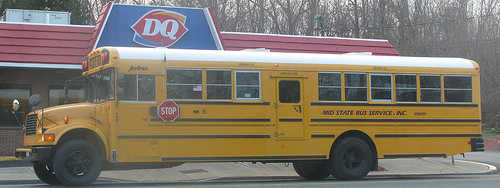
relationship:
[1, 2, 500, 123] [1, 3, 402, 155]
trees behind building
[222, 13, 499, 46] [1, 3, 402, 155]
wire behind building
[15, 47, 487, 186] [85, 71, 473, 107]
bus has windows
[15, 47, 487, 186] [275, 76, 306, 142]
bus has door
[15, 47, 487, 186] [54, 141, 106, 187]
bus has tire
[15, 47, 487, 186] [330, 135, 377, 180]
bus has tire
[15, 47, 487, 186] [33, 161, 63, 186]
bus has tire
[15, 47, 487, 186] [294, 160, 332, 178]
bus has tire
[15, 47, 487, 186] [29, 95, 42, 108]
bus has mirror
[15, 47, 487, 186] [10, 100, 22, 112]
bus has mirror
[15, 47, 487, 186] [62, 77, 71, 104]
bus has mirror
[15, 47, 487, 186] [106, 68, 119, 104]
bus has mirror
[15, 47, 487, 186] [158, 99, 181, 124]
bus h stop sign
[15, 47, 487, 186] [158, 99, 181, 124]
bus has stop sign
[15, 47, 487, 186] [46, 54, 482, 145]
bus has lights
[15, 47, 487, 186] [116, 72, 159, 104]
bus has driver's window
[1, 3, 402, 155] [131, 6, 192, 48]
building has dairy queen logo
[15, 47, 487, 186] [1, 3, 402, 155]
bus in front of building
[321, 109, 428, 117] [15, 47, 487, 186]
black print on side of bus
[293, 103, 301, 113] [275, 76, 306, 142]
handle attached to door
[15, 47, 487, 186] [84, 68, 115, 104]
bus has windshield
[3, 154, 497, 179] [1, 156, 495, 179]
sidewalk has yellow line